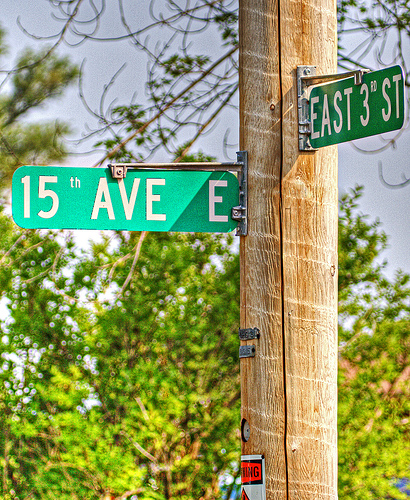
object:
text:
[239, 465, 259, 482]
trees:
[335, 197, 409, 500]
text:
[21, 171, 233, 225]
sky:
[0, 1, 407, 60]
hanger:
[294, 61, 369, 84]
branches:
[76, 53, 91, 117]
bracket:
[107, 160, 248, 181]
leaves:
[166, 313, 182, 336]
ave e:
[89, 173, 232, 225]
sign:
[10, 164, 242, 235]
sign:
[237, 452, 264, 499]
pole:
[237, 2, 339, 499]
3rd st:
[357, 75, 404, 127]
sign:
[305, 64, 403, 150]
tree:
[0, 25, 84, 194]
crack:
[272, 2, 295, 499]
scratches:
[313, 180, 318, 247]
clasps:
[237, 326, 261, 341]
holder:
[106, 156, 251, 236]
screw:
[306, 69, 310, 76]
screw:
[243, 419, 251, 442]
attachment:
[295, 64, 367, 153]